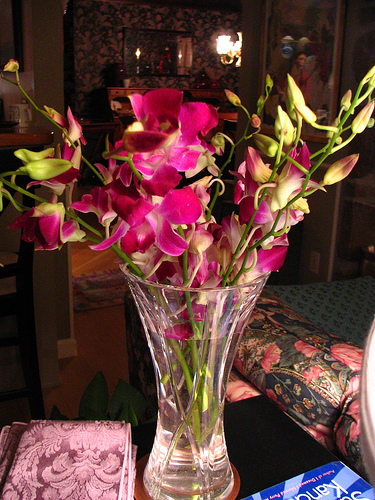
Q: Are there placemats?
A: No, there are no placemats.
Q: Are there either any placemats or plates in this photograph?
A: No, there are no placemats or plates.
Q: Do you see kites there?
A: No, there are no kites.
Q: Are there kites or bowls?
A: No, there are no kites or bowls.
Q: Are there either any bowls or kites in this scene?
A: No, there are no kites or bowls.